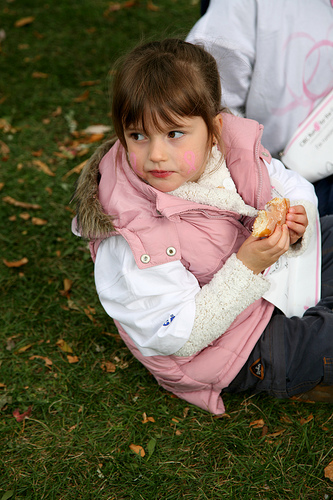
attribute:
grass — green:
[2, 2, 332, 499]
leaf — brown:
[4, 254, 29, 271]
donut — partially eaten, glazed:
[251, 197, 290, 239]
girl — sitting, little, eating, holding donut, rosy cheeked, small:
[65, 36, 332, 417]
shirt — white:
[184, 1, 332, 156]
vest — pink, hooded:
[70, 112, 278, 421]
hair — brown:
[108, 35, 224, 153]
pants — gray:
[221, 214, 332, 399]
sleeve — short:
[93, 236, 199, 359]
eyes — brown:
[126, 128, 190, 143]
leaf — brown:
[99, 359, 117, 375]